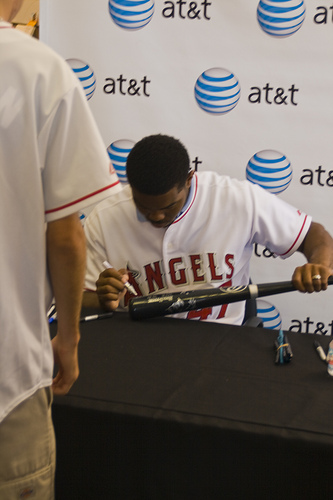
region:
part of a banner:
[157, 34, 186, 57]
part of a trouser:
[9, 419, 34, 448]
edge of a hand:
[59, 303, 75, 375]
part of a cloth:
[201, 408, 242, 446]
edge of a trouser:
[34, 423, 58, 470]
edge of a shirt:
[2, 385, 31, 414]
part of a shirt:
[0, 327, 26, 368]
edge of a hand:
[63, 327, 76, 353]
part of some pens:
[268, 316, 297, 387]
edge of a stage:
[212, 395, 265, 449]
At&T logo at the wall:
[163, 63, 319, 148]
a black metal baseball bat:
[128, 274, 331, 317]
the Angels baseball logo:
[120, 253, 237, 305]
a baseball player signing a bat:
[81, 133, 331, 325]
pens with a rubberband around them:
[273, 325, 295, 364]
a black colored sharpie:
[311, 336, 327, 363]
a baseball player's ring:
[311, 273, 321, 281]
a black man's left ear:
[182, 167, 195, 186]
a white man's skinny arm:
[44, 206, 87, 393]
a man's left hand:
[292, 263, 332, 293]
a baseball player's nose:
[150, 205, 166, 222]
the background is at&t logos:
[191, 45, 326, 127]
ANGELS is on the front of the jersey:
[122, 251, 262, 291]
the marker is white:
[101, 254, 141, 301]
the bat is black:
[89, 260, 326, 332]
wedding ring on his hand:
[289, 262, 331, 299]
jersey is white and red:
[98, 200, 327, 349]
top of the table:
[114, 317, 331, 439]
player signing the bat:
[96, 265, 194, 321]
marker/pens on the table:
[273, 327, 331, 375]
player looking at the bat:
[116, 138, 207, 245]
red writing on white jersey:
[109, 233, 238, 318]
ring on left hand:
[304, 266, 324, 286]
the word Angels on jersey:
[99, 240, 235, 312]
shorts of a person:
[2, 397, 81, 493]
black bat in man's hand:
[128, 264, 315, 343]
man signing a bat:
[92, 156, 302, 316]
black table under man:
[144, 329, 247, 396]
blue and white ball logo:
[185, 71, 246, 120]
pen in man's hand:
[100, 261, 142, 306]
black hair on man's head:
[136, 129, 191, 194]